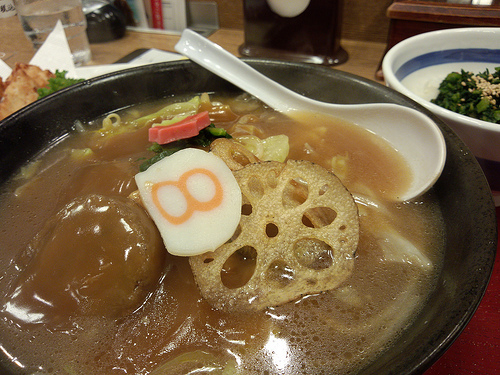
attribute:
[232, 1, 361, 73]
holder — wooden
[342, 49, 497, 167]
bowl — white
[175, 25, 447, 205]
spoon — white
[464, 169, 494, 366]
place mat — red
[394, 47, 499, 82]
ring — blue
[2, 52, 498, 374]
bowl — black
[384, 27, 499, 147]
bowl — white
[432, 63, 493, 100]
leaves — green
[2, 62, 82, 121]
sandwich — tasty looking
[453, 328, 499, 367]
napkin — red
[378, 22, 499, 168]
bowl — white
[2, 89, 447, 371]
stew — delicious looking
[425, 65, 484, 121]
vegetable — green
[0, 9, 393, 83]
table — wooden